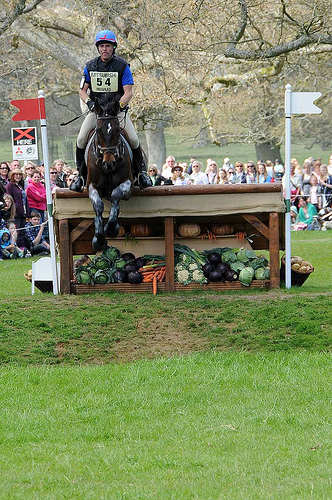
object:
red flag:
[10, 97, 46, 124]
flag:
[289, 92, 321, 114]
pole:
[37, 86, 59, 295]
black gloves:
[86, 99, 98, 117]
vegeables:
[104, 239, 116, 265]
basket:
[281, 252, 312, 286]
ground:
[233, 116, 260, 142]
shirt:
[83, 58, 136, 87]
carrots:
[140, 258, 171, 295]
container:
[72, 281, 164, 290]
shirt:
[26, 178, 46, 211]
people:
[150, 154, 329, 198]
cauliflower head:
[191, 270, 200, 280]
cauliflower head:
[176, 268, 190, 283]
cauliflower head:
[189, 261, 197, 271]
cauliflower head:
[175, 261, 186, 271]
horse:
[83, 92, 134, 251]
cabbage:
[238, 267, 253, 286]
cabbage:
[254, 266, 272, 281]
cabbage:
[220, 247, 236, 262]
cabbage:
[235, 246, 254, 261]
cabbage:
[249, 258, 267, 269]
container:
[172, 206, 278, 286]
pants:
[76, 110, 139, 150]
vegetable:
[210, 268, 224, 278]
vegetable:
[206, 248, 222, 265]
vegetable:
[175, 265, 191, 283]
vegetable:
[126, 268, 143, 283]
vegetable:
[93, 266, 109, 284]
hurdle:
[53, 184, 287, 296]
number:
[95, 76, 113, 86]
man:
[72, 28, 154, 195]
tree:
[0, 0, 86, 166]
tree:
[119, 0, 203, 179]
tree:
[222, 0, 330, 169]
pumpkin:
[211, 220, 236, 234]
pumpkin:
[177, 223, 200, 236]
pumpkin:
[130, 221, 150, 240]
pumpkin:
[115, 224, 126, 236]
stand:
[53, 182, 285, 296]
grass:
[0, 229, 330, 499]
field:
[0, 230, 331, 498]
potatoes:
[285, 254, 312, 273]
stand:
[283, 82, 291, 289]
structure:
[52, 183, 282, 294]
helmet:
[91, 27, 118, 50]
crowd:
[147, 152, 332, 232]